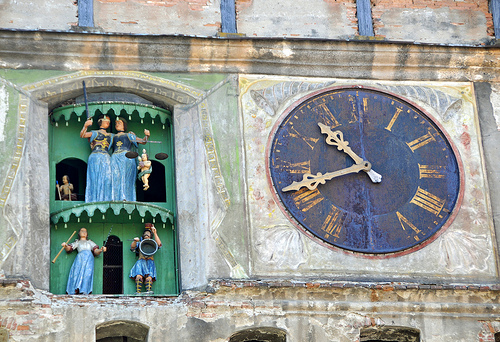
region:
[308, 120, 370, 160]
Short hand on clock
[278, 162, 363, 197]
Long hand on clock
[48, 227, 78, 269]
Stick in woman's hand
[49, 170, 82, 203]
Boy sitting in window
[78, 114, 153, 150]
Ladies hugging each other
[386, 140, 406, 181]
Blue color on clock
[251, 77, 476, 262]
Blue and gold clock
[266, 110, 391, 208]
Grey hands on clock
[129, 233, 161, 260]
Shield in man's hand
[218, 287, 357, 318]
Grey stone wall under clock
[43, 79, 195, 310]
scene on the side of a building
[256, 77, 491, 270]
clock face with roman numerals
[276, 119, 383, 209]
ornate gold clock hands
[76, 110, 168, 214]
two people in blue robes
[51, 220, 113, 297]
person in a blue robe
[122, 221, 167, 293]
person in a blue robe with a drum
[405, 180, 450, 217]
gold roman numeral four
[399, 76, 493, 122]
faded paint on the side of a building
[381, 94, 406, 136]
gold roman numeral one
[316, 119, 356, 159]
ornate pointer on the clock hand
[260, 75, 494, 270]
clock has roman numerals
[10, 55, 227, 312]
figurines standing next to clock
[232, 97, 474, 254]
roman numerals are gold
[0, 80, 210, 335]
figurine's outfits are blue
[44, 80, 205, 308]
the wall is green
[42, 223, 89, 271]
figuring holding brown stick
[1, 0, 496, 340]
paint chipping off walls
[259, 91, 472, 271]
roman numerals are fading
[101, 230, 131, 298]
black door between figurines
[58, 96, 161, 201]
figurines are looking at each other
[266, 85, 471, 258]
Large clock on the building.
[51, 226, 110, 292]
Statue of a woman holding a stick.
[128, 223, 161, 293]
Statue of a man with a round object.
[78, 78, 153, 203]
Statue of two women.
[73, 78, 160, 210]
Women holding up a puppet.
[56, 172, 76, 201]
Small statue of a man.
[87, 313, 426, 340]
Cut out of windows on the building.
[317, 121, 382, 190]
Small hand on the clock.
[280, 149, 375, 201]
Large hand of the clock.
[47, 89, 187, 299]
Cut out in building that is green.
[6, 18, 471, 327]
an unsual clock tower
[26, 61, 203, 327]
a dramatic scene on display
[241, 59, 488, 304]
a large Roman numeral clock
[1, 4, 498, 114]
an old stone building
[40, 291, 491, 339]
window openings can barely be seen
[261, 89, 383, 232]
the time on this clock is 10:42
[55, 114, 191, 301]
most of the figurines are wearing blue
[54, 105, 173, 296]
the figurine's stage is green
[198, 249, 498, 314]
the stone on the building is chipping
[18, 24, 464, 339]
this must be a classic building